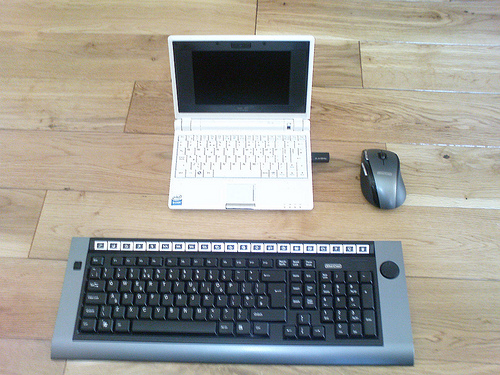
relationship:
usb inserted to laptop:
[307, 147, 336, 168] [160, 29, 328, 235]